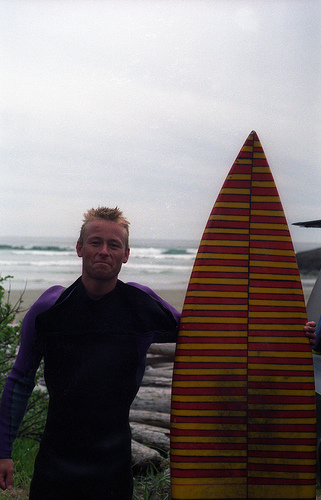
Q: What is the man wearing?
A: A wetsuit.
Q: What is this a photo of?
A: A blonde surfer with a surfboard.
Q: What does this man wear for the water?
A: A wetsuit.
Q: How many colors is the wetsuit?
A: Two.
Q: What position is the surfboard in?
A: Vertical position.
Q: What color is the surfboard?
A: Red and yellow.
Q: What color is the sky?
A: Blue with white clouds.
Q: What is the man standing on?
A: Sand.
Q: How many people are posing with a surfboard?
A: One man.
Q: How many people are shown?
A: 1.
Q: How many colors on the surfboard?
A: 3.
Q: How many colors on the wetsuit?
A: 2.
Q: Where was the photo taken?
A: Beach.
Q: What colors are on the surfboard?
A: Red, Yellow and black.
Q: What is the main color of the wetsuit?
A: Black.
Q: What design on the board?
A: Stripes.